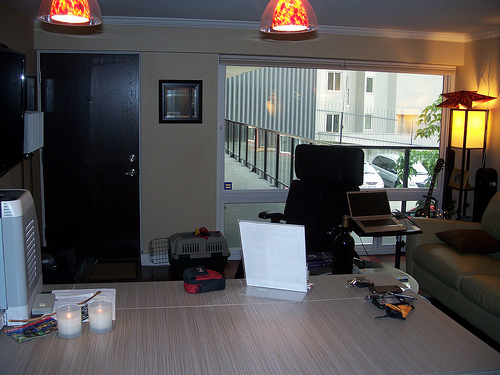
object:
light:
[33, 0, 104, 35]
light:
[257, 0, 321, 43]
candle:
[56, 299, 82, 339]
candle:
[86, 297, 114, 334]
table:
[1, 269, 499, 374]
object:
[366, 294, 413, 320]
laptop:
[346, 189, 407, 236]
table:
[346, 215, 424, 268]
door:
[39, 51, 141, 281]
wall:
[34, 21, 473, 284]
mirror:
[157, 78, 202, 126]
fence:
[225, 116, 438, 210]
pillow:
[434, 228, 498, 254]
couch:
[403, 189, 499, 359]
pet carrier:
[196, 225, 214, 240]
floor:
[43, 254, 408, 284]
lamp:
[445, 107, 489, 220]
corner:
[446, 43, 492, 222]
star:
[435, 90, 498, 111]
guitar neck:
[421, 157, 443, 217]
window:
[223, 66, 449, 208]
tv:
[1, 42, 25, 178]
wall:
[1, 1, 43, 279]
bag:
[181, 263, 225, 294]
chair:
[234, 143, 364, 279]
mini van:
[371, 153, 433, 188]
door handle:
[125, 167, 136, 178]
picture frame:
[23, 74, 38, 110]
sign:
[223, 180, 234, 192]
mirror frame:
[157, 76, 204, 125]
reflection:
[263, 90, 303, 115]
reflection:
[392, 111, 427, 128]